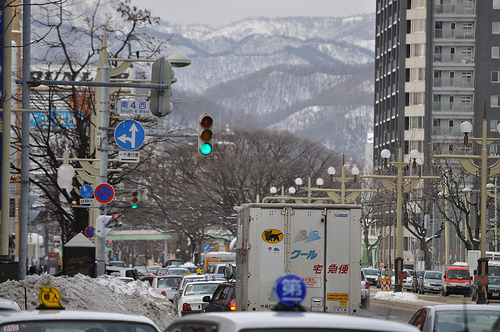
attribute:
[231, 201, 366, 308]
truck — white, commercial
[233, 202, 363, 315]
truck — large, white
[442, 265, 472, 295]
van — parked, red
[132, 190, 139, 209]
traffic light — hanging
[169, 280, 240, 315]
car — white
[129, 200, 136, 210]
light — green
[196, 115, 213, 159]
signal — electric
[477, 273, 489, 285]
road sign — red, green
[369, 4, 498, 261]
building — tall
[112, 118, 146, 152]
sign — white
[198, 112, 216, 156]
traffic light — green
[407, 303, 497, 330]
car — silver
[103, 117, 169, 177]
sign — red, blue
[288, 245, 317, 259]
chinese writing — blue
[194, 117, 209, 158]
light — green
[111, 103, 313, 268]
trees — Bare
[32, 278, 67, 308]
sign — yellow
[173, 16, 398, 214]
mountain — distant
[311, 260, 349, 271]
writing — red, Chinese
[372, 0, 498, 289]
building — tall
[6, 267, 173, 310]
snow — dirty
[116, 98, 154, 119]
sign — Chinese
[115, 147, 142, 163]
sign — Chinese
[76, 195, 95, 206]
sign — Chinese